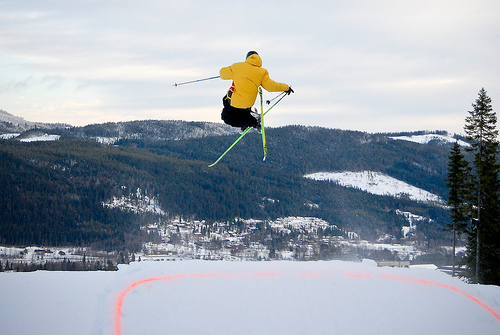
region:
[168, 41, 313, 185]
a skier in midair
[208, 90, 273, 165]
yellow neon skis in the air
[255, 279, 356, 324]
white snow on the mountain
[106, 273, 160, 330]
red painted line in the snow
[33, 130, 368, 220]
many pine trees growing on the hills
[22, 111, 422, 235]
snowy rolling hills in the distance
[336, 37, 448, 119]
white cloudy skies over the hills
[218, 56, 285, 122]
the skier's yellow jacket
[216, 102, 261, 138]
the skier's black snow pants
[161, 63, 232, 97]
a black ski pole in the air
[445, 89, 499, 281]
small group of pine trees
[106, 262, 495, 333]
bright orange painted lines in the snow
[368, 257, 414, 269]
top of a small white building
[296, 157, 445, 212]
white clearing on the mountainside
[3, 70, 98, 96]
light grey clouds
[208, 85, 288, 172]
pair of bright green skis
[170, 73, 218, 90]
blue and white ski pole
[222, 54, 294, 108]
bright yellow ski jacket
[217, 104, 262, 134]
black ski pants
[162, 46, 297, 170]
skier performing a jump with crossed skis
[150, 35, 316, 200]
skier doing trick in air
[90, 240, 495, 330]
bright orange paint on snow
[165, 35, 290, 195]
person wearing green ski's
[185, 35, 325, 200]
person wearing yellow jacket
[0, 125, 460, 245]
thick forest covering most of mountain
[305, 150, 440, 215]
large patch of snow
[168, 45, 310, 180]
person flying through the air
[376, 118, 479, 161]
snowcap on hill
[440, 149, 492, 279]
trees on top of hill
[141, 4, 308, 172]
person wearing ski gear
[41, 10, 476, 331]
A person is up in the mountains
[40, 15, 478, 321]
Someone is enjoying the winter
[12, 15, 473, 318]
A person is enjoying the view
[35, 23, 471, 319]
A skier is making a jump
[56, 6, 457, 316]
A person is in the air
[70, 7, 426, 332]
A skier is doing a stunt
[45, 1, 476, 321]
A person has skis on their feet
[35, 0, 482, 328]
A person is holding ski poles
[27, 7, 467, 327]
A person is wearing a heavy jacket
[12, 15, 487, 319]
A person is in the snow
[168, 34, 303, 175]
A skier performing a trick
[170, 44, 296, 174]
A skier in a yellow parka and black pants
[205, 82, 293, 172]
Skis crossed in a jump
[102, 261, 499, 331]
Bright paint on snow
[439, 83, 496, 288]
Tall trees in winter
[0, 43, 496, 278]
A skier jumping in front of mountains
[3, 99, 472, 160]
The ridge of a mountain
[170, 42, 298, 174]
A competitive skier performing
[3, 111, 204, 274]
Trees on a snowy mountainside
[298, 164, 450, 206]
A clearing on a mountainside